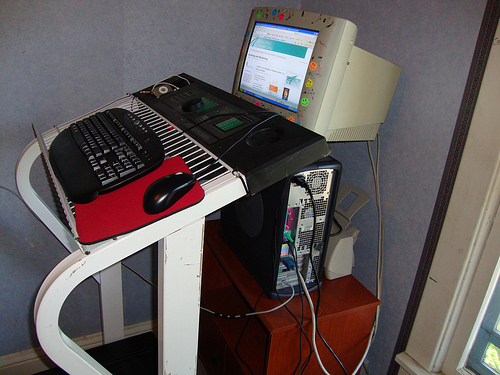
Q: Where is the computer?
A: Top of a stand.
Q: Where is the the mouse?
A: On a mouse pad.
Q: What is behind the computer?
A: A printer.